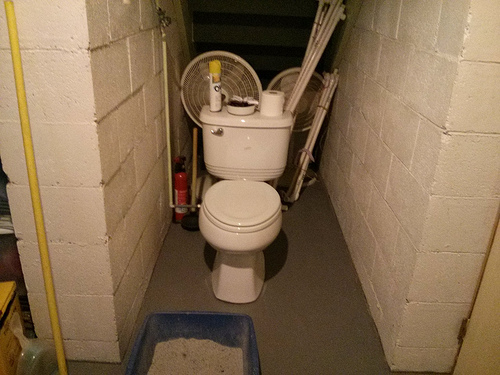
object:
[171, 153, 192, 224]
fire extinguisher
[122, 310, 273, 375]
litter box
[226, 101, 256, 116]
ashtray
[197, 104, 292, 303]
toilet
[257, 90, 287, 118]
toilet paper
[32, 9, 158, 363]
wall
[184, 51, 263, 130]
fan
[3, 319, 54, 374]
dust pan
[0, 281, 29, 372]
box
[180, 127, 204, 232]
plunger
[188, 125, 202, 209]
handle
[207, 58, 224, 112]
can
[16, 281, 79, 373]
corner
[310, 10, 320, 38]
lighbulbs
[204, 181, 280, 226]
lid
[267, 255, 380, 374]
ground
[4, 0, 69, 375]
pole